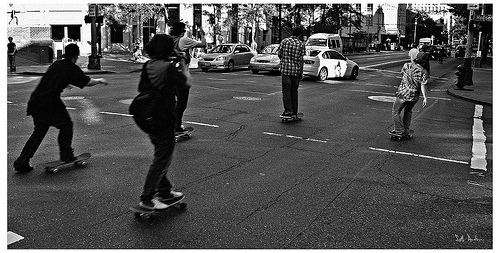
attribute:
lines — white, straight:
[209, 108, 401, 168]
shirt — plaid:
[268, 29, 330, 84]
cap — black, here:
[59, 37, 97, 60]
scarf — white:
[402, 45, 432, 71]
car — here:
[305, 46, 366, 82]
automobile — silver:
[204, 34, 251, 64]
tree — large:
[113, 7, 151, 40]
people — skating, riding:
[86, 16, 433, 153]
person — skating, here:
[269, 23, 322, 113]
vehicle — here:
[252, 34, 280, 84]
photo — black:
[71, 7, 390, 176]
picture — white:
[193, 16, 393, 181]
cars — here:
[218, 30, 378, 105]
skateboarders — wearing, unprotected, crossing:
[65, 12, 321, 120]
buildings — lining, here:
[100, 5, 398, 51]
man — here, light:
[390, 42, 444, 118]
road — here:
[197, 78, 281, 197]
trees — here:
[205, 7, 366, 36]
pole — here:
[445, 8, 495, 93]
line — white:
[388, 139, 490, 179]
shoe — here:
[59, 134, 93, 168]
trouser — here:
[384, 96, 427, 132]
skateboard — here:
[48, 147, 70, 179]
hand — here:
[98, 67, 120, 82]